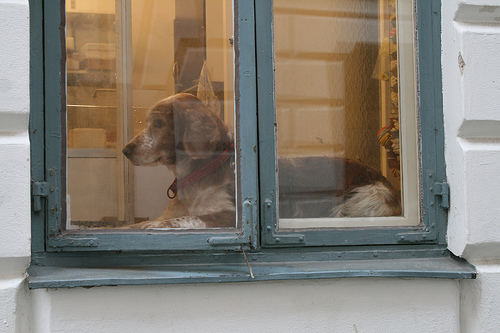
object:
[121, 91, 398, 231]
dog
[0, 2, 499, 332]
house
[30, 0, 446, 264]
frame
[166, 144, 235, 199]
collar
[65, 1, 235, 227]
window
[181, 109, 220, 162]
ear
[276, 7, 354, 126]
wall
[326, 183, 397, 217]
tail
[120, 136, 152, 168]
nose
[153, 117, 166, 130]
eye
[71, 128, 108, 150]
box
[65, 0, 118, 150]
shelf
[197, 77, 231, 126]
cloth